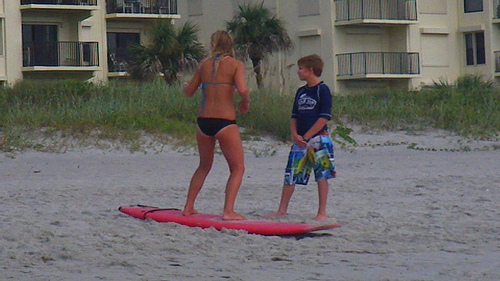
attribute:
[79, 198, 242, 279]
sand — grey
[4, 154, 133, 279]
sand — grey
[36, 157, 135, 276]
sand — grey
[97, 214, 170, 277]
sand — grey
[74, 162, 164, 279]
sand — grey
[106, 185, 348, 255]
surfboard — pink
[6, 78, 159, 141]
grass — tall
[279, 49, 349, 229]
boy — young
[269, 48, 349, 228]
boy — young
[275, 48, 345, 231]
boy — young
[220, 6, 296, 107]
tree — palm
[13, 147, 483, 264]
sand — light grey, beach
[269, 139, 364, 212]
board shorts — blue, multicolored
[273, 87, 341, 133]
tshirt — dark blue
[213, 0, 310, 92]
tree — short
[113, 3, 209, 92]
tree — short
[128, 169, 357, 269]
surfboard — red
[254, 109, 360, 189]
swim shorts — colorful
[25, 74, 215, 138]
grass — tall, green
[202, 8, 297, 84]
tree — green, tall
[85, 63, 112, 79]
chair — white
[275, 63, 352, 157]
shirt — blue, short sleeve